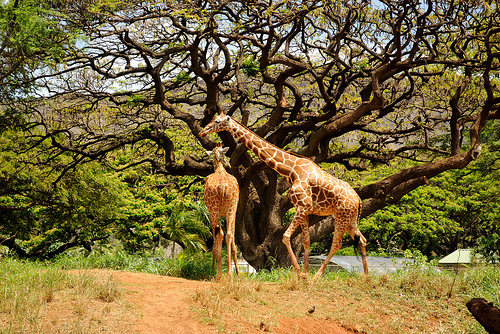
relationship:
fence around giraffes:
[245, 240, 490, 275] [202, 109, 356, 308]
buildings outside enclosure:
[441, 240, 499, 270] [22, 48, 485, 315]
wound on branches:
[435, 137, 487, 192] [115, 7, 469, 99]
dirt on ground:
[141, 282, 287, 331] [32, 267, 430, 334]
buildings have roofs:
[441, 240, 499, 270] [440, 242, 477, 265]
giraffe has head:
[201, 149, 250, 272] [209, 134, 228, 170]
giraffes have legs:
[202, 109, 356, 308] [288, 190, 356, 271]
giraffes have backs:
[202, 109, 356, 308] [308, 151, 371, 217]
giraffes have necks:
[202, 109, 356, 308] [216, 118, 250, 177]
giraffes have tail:
[202, 109, 356, 308] [209, 185, 229, 237]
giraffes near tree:
[202, 109, 356, 308] [48, 12, 483, 267]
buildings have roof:
[441, 240, 499, 270] [440, 242, 477, 265]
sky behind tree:
[85, 22, 235, 79] [48, 12, 483, 267]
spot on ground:
[240, 312, 274, 333] [32, 267, 430, 334]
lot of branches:
[67, 14, 483, 110] [115, 7, 469, 99]